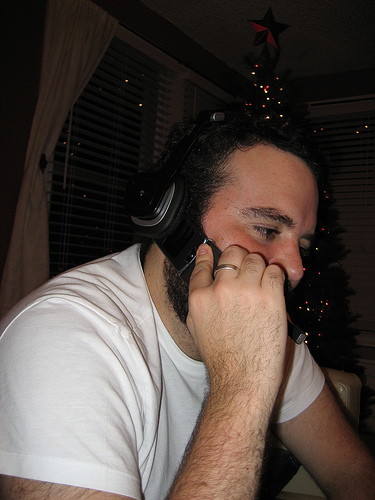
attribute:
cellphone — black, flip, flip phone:
[129, 188, 226, 301]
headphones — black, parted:
[134, 115, 341, 233]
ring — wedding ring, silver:
[213, 246, 246, 294]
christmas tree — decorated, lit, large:
[254, 65, 279, 114]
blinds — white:
[113, 81, 149, 136]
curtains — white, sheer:
[57, 32, 93, 85]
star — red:
[249, 14, 298, 59]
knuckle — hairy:
[179, 282, 301, 326]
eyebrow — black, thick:
[238, 193, 303, 234]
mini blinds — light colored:
[337, 114, 362, 161]